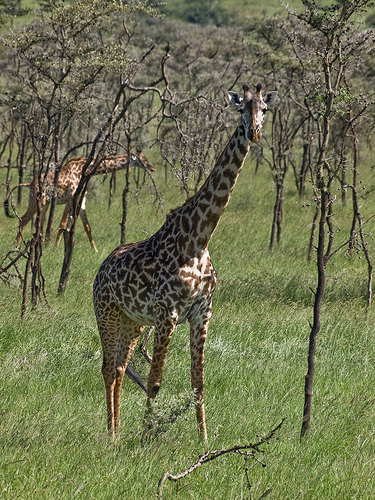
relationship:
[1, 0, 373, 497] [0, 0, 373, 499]
trees in field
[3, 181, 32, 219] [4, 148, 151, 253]
tail of giraffe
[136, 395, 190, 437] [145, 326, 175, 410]
bush between giraffe's leg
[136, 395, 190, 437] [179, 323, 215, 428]
bush between giraffe's leg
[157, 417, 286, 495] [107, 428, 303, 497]
branch lying in grass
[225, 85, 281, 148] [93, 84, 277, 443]
head on a giraffe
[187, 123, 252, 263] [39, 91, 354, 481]
neck on a giraffe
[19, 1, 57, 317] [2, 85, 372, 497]
tall tree in grass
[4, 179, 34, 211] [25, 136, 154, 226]
tail on giraffe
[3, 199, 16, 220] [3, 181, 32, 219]
hair on tail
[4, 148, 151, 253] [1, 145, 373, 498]
giraffe by grass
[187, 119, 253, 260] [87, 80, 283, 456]
neck on giraffe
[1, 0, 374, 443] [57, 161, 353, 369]
trees on grass